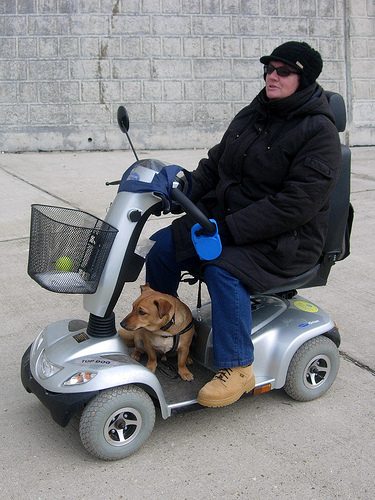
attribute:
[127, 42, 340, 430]
lady — sitting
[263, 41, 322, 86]
hat — black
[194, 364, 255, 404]
boot — brown, big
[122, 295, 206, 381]
dog — brown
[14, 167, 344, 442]
scooter — mini, grey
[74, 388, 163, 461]
front tire — small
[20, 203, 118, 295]
basket — black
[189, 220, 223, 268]
leash — retractable, blue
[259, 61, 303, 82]
sunglasses — black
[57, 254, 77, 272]
ball — green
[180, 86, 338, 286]
jacket — warm, black, large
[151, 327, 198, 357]
harness — black